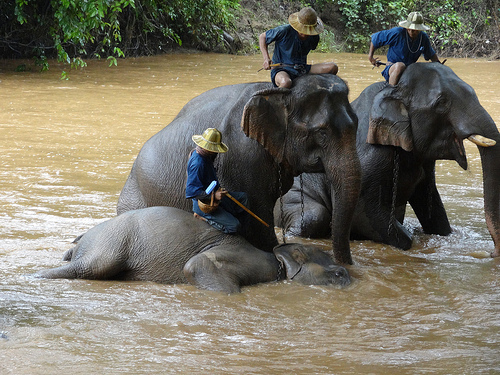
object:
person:
[368, 12, 442, 86]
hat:
[397, 11, 430, 32]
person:
[258, 6, 338, 88]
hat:
[286, 7, 323, 36]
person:
[185, 127, 250, 233]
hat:
[190, 127, 228, 155]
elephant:
[34, 204, 353, 296]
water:
[1, 51, 499, 374]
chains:
[388, 149, 403, 247]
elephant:
[274, 62, 499, 258]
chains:
[277, 163, 286, 243]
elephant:
[117, 73, 362, 265]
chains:
[277, 262, 281, 281]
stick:
[220, 187, 271, 228]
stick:
[257, 62, 282, 73]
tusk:
[468, 133, 497, 146]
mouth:
[450, 129, 480, 171]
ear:
[273, 242, 309, 280]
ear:
[366, 86, 413, 152]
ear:
[239, 89, 289, 165]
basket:
[198, 191, 219, 214]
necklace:
[406, 31, 423, 53]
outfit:
[372, 28, 436, 81]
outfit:
[265, 24, 319, 87]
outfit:
[185, 152, 249, 233]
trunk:
[472, 107, 498, 258]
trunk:
[319, 152, 361, 265]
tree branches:
[1, 1, 234, 83]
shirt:
[185, 152, 221, 201]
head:
[273, 242, 352, 289]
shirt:
[372, 27, 435, 65]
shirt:
[264, 27, 318, 67]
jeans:
[192, 191, 249, 235]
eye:
[437, 97, 448, 107]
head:
[242, 72, 363, 264]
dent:
[293, 91, 329, 126]